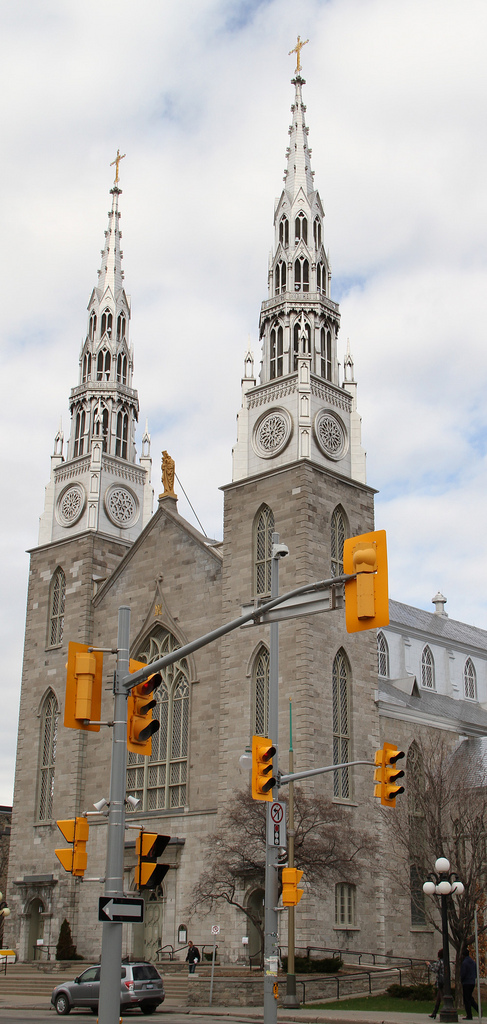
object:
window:
[113, 619, 190, 811]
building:
[78, 449, 223, 972]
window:
[34, 687, 59, 822]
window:
[46, 566, 68, 649]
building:
[15, 531, 136, 761]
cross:
[109, 148, 126, 181]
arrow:
[100, 896, 143, 921]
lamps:
[422, 859, 464, 898]